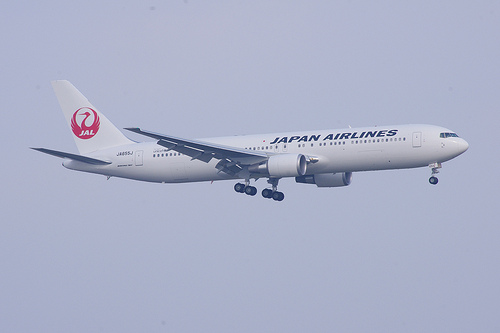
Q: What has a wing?
A: The airplane.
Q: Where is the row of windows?
A: On the side of the plane.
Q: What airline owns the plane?
A: Japan Airlines.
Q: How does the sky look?
A: Overcast.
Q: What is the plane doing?
A: Flying.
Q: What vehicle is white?
A: The plane.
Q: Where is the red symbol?
A: On the plane's tail.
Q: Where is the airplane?
A: In the air.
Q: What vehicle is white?
A: The airplane.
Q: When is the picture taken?
A: Daytime.